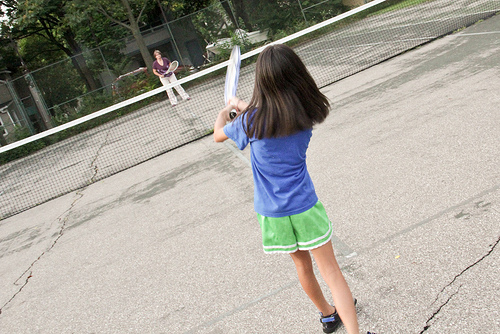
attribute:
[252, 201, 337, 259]
shorts — green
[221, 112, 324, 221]
shirt — blue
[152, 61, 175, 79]
shirt — purple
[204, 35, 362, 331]
female — playing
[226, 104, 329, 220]
shirt — blue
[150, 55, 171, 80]
shirt — purple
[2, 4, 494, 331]
court — cracked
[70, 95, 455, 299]
court — concrete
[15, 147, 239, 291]
concrete — cracked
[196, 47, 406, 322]
girl — young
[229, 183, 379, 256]
shorts — green, white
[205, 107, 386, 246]
top — blue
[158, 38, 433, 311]
girl — playing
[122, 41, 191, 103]
woman — playing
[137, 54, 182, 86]
coat — purple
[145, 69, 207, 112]
pants — white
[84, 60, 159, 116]
vehicle — red, parked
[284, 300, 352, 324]
shoe — black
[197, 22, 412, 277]
girl — young, playing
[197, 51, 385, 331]
girl — young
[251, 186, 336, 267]
shorts — green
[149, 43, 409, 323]
girl — young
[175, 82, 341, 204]
shirt — blue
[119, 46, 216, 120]
lady — playing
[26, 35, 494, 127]
net — dividing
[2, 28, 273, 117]
fence — chainlink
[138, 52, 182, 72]
shirt — red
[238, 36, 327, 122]
hair — dark, medium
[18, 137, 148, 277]
court — cracked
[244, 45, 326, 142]
hair — long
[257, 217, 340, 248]
shorts — green